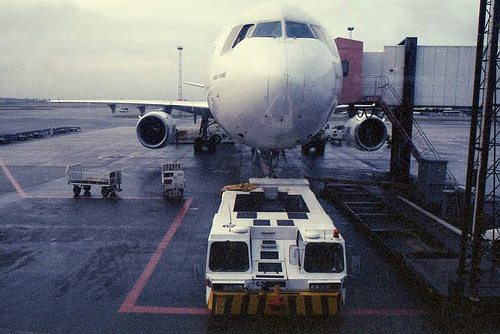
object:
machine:
[200, 174, 352, 319]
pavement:
[13, 103, 496, 332]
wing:
[48, 100, 209, 112]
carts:
[161, 162, 187, 201]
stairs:
[375, 74, 460, 184]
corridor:
[329, 34, 490, 114]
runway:
[2, 103, 176, 324]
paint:
[204, 287, 342, 317]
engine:
[135, 110, 180, 149]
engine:
[342, 107, 387, 152]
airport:
[45, 2, 391, 176]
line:
[2, 158, 454, 318]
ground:
[13, 105, 491, 328]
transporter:
[64, 163, 124, 197]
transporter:
[328, 34, 497, 114]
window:
[231, 23, 251, 48]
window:
[253, 18, 282, 38]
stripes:
[212, 291, 341, 315]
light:
[332, 228, 339, 238]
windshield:
[253, 18, 312, 39]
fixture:
[267, 285, 288, 311]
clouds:
[2, 0, 495, 100]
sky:
[2, 3, 498, 98]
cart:
[64, 163, 123, 196]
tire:
[109, 191, 115, 194]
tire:
[175, 191, 185, 201]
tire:
[161, 186, 168, 196]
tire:
[194, 138, 203, 152]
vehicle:
[193, 136, 218, 157]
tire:
[206, 140, 216, 154]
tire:
[71, 185, 83, 194]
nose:
[209, 11, 359, 125]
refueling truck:
[205, 166, 349, 324]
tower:
[167, 35, 209, 109]